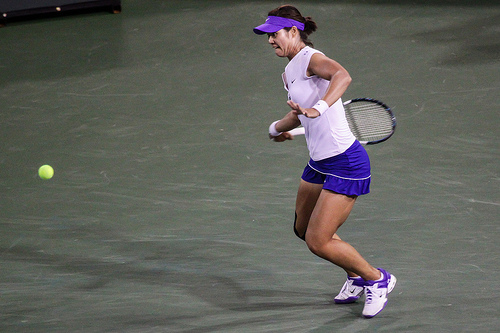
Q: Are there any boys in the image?
A: No, there are no boys.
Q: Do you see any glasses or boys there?
A: No, there are no boys or glasses.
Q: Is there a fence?
A: No, there are no fences.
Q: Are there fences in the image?
A: No, there are no fences.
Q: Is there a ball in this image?
A: Yes, there is a ball.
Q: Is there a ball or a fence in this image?
A: Yes, there is a ball.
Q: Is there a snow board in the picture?
A: No, there are no snowboards.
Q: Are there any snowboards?
A: No, there are no snowboards.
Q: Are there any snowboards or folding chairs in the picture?
A: No, there are no snowboards or folding chairs.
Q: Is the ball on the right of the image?
A: No, the ball is on the left of the image.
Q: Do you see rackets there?
A: Yes, there is a racket.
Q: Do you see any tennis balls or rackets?
A: Yes, there is a racket.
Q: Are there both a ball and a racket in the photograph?
A: Yes, there are both a racket and a ball.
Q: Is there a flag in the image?
A: No, there are no flags.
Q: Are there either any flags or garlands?
A: No, there are no flags or garlands.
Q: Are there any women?
A: Yes, there is a woman.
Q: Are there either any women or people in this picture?
A: Yes, there is a woman.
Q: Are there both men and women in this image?
A: No, there is a woman but no men.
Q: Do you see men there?
A: No, there are no men.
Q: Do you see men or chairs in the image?
A: No, there are no men or chairs.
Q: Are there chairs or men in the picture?
A: No, there are no men or chairs.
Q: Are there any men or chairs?
A: No, there are no men or chairs.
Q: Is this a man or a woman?
A: This is a woman.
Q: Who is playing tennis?
A: The woman is playing tennis.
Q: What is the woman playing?
A: The woman is playing tennis.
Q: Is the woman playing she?
A: Yes, the woman is playing tennis.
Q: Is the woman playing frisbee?
A: No, the woman is playing tennis.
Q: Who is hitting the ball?
A: The woman is hitting the ball.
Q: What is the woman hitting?
A: The woman is hitting the ball.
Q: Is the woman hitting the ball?
A: Yes, the woman is hitting the ball.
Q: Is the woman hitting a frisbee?
A: No, the woman is hitting the ball.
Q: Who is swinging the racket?
A: The woman is swinging the racket.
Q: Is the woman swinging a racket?
A: Yes, the woman is swinging a racket.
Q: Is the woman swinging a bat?
A: No, the woman is swinging a racket.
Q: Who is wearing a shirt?
A: The woman is wearing a shirt.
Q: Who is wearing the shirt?
A: The woman is wearing a shirt.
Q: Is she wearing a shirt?
A: Yes, the woman is wearing a shirt.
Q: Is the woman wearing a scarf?
A: No, the woman is wearing a shirt.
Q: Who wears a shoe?
A: The woman wears a shoe.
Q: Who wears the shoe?
A: The woman wears a shoe.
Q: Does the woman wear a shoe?
A: Yes, the woman wears a shoe.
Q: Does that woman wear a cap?
A: No, the woman wears a shoe.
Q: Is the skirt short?
A: Yes, the skirt is short.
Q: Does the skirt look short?
A: Yes, the skirt is short.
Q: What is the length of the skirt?
A: The skirt is short.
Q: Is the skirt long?
A: No, the skirt is short.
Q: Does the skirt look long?
A: No, the skirt is short.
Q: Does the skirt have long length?
A: No, the skirt is short.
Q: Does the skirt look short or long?
A: The skirt is short.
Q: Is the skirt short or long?
A: The skirt is short.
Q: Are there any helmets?
A: No, there are no helmets.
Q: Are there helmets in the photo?
A: No, there are no helmets.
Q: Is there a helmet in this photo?
A: No, there are no helmets.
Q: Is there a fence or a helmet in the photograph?
A: No, there are no helmets or fences.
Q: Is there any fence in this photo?
A: No, there are no fences.